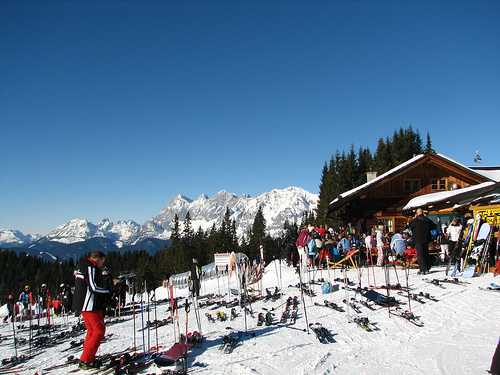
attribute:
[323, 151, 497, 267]
lodge — wooden, large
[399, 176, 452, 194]
windows — small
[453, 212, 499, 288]
snowboards — colorful, leaning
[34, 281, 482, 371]
snow — packed, white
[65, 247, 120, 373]
man — stopped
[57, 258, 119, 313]
coat — black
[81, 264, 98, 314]
stripes — white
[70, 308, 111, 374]
pants — red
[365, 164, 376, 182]
chimney — gray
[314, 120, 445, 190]
trees — green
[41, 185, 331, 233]
mountains — gray, tall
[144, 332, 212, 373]
board — dark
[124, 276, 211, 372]
poles — slim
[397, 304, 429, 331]
skis — white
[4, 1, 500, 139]
skies — blue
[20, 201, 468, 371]
people — gathered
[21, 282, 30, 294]
helmet — gold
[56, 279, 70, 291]
helmet — white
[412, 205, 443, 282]
man — bald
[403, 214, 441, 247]
coat — black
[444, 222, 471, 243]
coat — white